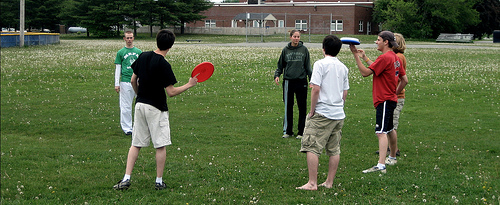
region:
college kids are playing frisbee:
[13, 6, 489, 198]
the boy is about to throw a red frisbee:
[127, 30, 214, 150]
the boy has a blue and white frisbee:
[333, 29, 401, 179]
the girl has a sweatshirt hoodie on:
[268, 26, 315, 96]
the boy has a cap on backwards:
[373, 28, 399, 65]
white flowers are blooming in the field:
[6, 40, 496, 202]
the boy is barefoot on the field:
[293, 37, 350, 193]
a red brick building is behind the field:
[101, 2, 376, 41]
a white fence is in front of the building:
[186, 22, 301, 47]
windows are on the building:
[189, 12, 372, 40]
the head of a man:
[144, 19, 184, 65]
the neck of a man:
[140, 38, 172, 65]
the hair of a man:
[146, 29, 179, 63]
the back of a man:
[124, 20, 188, 116]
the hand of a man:
[184, 60, 208, 100]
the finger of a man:
[182, 63, 213, 96]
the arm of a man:
[151, 66, 195, 122]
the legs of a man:
[113, 100, 190, 185]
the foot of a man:
[104, 143, 230, 198]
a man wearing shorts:
[119, 72, 204, 162]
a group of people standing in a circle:
[96, 18, 425, 193]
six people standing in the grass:
[100, 11, 434, 203]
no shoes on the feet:
[288, 175, 338, 195]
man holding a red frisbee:
[108, 22, 213, 192]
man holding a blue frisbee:
[336, 20, 409, 177]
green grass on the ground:
[1, 33, 498, 204]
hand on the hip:
[301, 105, 319, 124]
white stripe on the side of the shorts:
[378, 100, 389, 135]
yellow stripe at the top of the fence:
[1, 30, 61, 37]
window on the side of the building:
[329, 15, 345, 34]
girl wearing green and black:
[277, 25, 302, 141]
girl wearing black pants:
[274, 73, 311, 144]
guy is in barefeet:
[288, 139, 353, 193]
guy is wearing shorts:
[282, 100, 368, 164]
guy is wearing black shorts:
[369, 103, 406, 150]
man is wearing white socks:
[88, 152, 193, 200]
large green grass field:
[412, 47, 478, 185]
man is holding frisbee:
[190, 57, 225, 95]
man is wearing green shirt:
[101, 40, 146, 88]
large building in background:
[224, 5, 379, 39]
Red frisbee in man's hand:
[186, 59, 215, 86]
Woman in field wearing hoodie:
[274, 28, 311, 140]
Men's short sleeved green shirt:
[114, 43, 141, 83]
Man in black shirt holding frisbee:
[111, 27, 216, 189]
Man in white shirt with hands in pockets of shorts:
[295, 34, 350, 193]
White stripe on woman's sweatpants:
[281, 79, 290, 134]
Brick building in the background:
[171, 0, 376, 36]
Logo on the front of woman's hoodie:
[286, 53, 301, 62]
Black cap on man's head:
[380, 30, 399, 45]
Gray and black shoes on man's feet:
[111, 178, 169, 190]